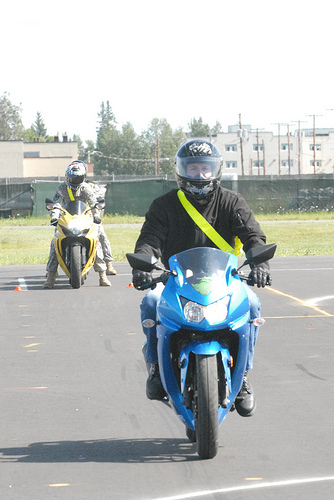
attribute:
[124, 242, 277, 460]
bike — blue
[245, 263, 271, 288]
glove — black, leather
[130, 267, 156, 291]
glove — black, leather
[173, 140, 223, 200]
helmet — black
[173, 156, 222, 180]
visor — clear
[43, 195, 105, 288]
motor bike — yellow, black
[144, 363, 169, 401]
boot — black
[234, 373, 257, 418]
boot — black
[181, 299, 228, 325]
headlight — dual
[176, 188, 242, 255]
strap — yellow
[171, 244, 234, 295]
windshield — useless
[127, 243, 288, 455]
motorcycle — blue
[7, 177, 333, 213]
tarp — green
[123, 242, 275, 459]
motorcycle — blue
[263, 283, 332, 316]
line — painted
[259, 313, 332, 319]
line — painted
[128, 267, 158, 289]
hand — gloved